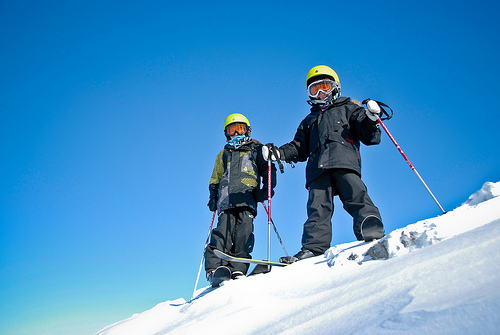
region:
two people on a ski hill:
[177, 78, 406, 243]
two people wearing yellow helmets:
[211, 72, 356, 134]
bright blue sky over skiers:
[98, 46, 400, 136]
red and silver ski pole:
[365, 100, 463, 220]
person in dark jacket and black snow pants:
[291, 77, 390, 263]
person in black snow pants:
[292, 55, 373, 237]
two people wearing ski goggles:
[212, 85, 389, 135]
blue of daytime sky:
[3, 3, 497, 331]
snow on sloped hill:
[112, 195, 496, 333]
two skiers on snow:
[191, 64, 443, 299]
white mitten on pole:
[360, 99, 446, 209]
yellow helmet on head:
[305, 65, 339, 102]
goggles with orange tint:
[226, 121, 247, 136]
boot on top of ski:
[215, 247, 313, 267]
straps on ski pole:
[366, 100, 393, 122]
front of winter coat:
[281, 101, 381, 181]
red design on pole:
[377, 114, 417, 171]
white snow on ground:
[150, 301, 183, 326]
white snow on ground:
[219, 297, 251, 327]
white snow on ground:
[273, 266, 296, 287]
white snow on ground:
[295, 287, 324, 317]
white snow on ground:
[451, 260, 481, 305]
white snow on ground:
[414, 292, 438, 325]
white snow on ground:
[468, 290, 494, 331]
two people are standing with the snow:
[172, 63, 451, 308]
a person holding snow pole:
[358, 85, 449, 227]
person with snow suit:
[268, 54, 392, 252]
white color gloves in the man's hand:
[365, 98, 380, 123]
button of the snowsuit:
[313, 156, 327, 171]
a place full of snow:
[330, 263, 430, 305]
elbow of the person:
[279, 128, 311, 164]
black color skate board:
[208, 247, 299, 274]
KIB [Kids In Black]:
[162, 46, 462, 315]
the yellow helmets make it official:
[216, 56, 351, 156]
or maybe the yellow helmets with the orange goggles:
[224, 81, 342, 151]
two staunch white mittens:
[257, 91, 398, 166]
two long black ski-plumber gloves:
[203, 162, 281, 214]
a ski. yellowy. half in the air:
[211, 243, 293, 274]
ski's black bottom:
[351, 214, 393, 247]